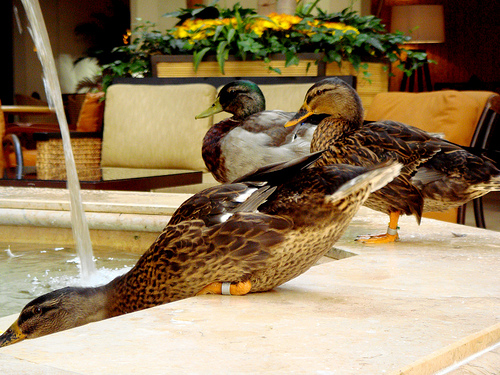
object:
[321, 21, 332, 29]
flowers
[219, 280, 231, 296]
rubber band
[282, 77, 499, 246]
duck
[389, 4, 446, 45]
shade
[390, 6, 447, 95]
lamp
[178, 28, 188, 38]
flower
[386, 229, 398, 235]
tag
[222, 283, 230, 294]
tag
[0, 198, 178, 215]
ledge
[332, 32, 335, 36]
flower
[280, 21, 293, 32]
flower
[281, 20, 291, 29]
flower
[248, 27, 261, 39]
flower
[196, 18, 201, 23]
flower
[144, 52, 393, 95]
pot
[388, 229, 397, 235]
strap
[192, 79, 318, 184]
duck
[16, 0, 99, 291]
fountain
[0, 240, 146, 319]
water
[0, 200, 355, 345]
pond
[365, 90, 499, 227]
chair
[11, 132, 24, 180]
stand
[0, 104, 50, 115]
table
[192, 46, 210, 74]
greenery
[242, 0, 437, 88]
planter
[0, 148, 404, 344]
duck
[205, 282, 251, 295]
leg